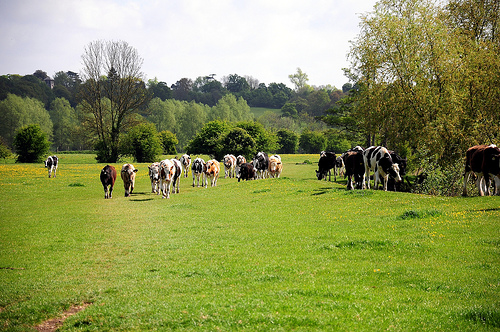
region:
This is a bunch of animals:
[42, 108, 324, 264]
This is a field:
[116, 218, 221, 328]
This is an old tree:
[45, 75, 126, 130]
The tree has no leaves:
[26, 54, 131, 137]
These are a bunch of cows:
[112, 105, 232, 272]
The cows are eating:
[304, 148, 446, 265]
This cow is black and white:
[328, 105, 461, 226]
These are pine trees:
[130, 53, 275, 125]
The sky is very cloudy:
[154, 30, 309, 72]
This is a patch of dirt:
[26, 293, 148, 328]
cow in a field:
[357, 141, 417, 191]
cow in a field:
[310, 145, 340, 175]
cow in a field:
[95, 145, 120, 190]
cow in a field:
[118, 160, 139, 205]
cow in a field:
[155, 155, 189, 200]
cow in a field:
[180, 155, 200, 180]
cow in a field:
[215, 150, 255, 185]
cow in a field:
[255, 140, 290, 180]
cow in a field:
[40, 141, 65, 176]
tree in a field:
[80, 25, 145, 152]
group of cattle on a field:
[79, 139, 404, 208]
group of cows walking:
[118, 142, 285, 224]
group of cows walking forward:
[43, 144, 285, 196]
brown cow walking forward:
[92, 161, 124, 194]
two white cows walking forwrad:
[149, 156, 177, 193]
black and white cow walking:
[343, 148, 403, 187]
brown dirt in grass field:
[21, 280, 101, 330]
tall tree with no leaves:
[63, 37, 138, 148]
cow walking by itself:
[27, 152, 64, 187]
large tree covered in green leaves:
[345, 2, 486, 137]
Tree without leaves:
[68, 33, 155, 163]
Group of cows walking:
[93, 150, 292, 200]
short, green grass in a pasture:
[156, 214, 326, 282]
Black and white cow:
[353, 142, 405, 191]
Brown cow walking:
[91, 159, 121, 199]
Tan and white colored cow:
[202, 159, 219, 191]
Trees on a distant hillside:
[5, 68, 320, 151]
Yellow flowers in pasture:
[1, 166, 39, 181]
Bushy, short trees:
[186, 115, 312, 156]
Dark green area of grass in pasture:
[391, 205, 445, 228]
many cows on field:
[89, 130, 348, 219]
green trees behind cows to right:
[341, 18, 491, 190]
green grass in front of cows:
[131, 200, 391, 285]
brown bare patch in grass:
[32, 280, 110, 330]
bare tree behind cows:
[89, 37, 144, 170]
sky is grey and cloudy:
[160, 14, 274, 71]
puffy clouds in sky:
[190, 3, 262, 64]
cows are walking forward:
[95, 138, 294, 201]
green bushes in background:
[120, 117, 360, 154]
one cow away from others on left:
[45, 157, 75, 194]